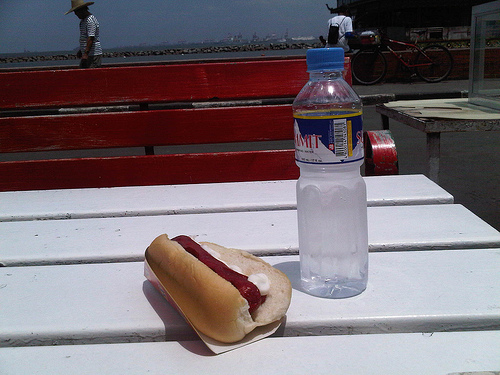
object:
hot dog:
[142, 232, 294, 345]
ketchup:
[172, 235, 258, 299]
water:
[296, 159, 368, 297]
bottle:
[290, 47, 370, 298]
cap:
[305, 48, 345, 71]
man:
[66, 2, 104, 65]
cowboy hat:
[64, 1, 95, 16]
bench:
[1, 57, 398, 193]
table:
[1, 173, 500, 373]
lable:
[291, 108, 364, 166]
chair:
[376, 1, 499, 184]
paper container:
[143, 260, 282, 354]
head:
[74, 6, 92, 20]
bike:
[349, 23, 455, 84]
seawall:
[1, 41, 329, 66]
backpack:
[326, 25, 341, 44]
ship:
[273, 36, 286, 44]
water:
[1, 41, 332, 72]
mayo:
[198, 241, 270, 294]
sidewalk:
[2, 97, 499, 231]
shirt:
[327, 14, 354, 51]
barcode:
[332, 117, 347, 156]